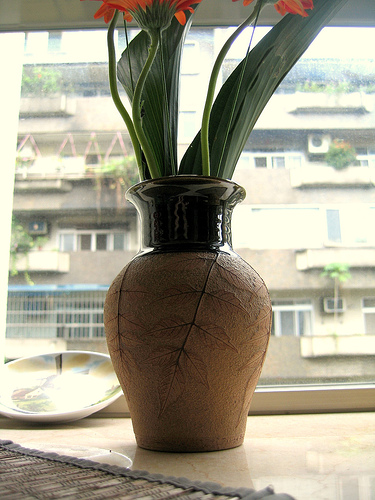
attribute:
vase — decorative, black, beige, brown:
[102, 176, 273, 453]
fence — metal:
[7, 292, 110, 363]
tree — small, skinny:
[321, 262, 354, 323]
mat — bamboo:
[0, 440, 296, 498]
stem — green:
[131, 30, 165, 179]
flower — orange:
[91, 0, 200, 35]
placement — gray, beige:
[1, 430, 296, 497]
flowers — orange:
[317, 123, 363, 156]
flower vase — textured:
[101, 170, 272, 453]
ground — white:
[299, 57, 344, 85]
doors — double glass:
[75, 233, 113, 253]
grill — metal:
[5, 291, 106, 338]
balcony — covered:
[4, 285, 109, 355]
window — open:
[1, 14, 371, 385]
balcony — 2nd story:
[12, 247, 73, 272]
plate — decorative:
[2, 348, 127, 427]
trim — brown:
[0, 437, 299, 499]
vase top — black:
[125, 174, 249, 253]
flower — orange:
[231, 0, 318, 17]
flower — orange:
[91, 0, 202, 25]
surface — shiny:
[0, 407, 374, 499]